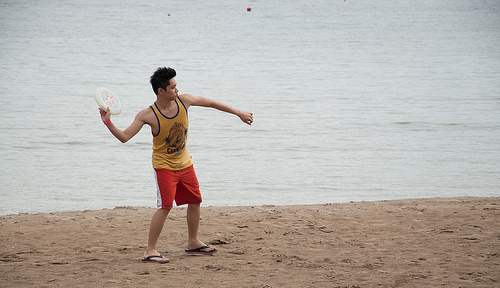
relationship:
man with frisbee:
[93, 66, 253, 263] [73, 57, 139, 134]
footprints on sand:
[0, 193, 494, 285] [359, 204, 480, 278]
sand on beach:
[0, 193, 495, 284] [1, 1, 498, 286]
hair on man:
[149, 65, 176, 97] [93, 66, 253, 263]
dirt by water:
[0, 194, 498, 286] [1, 0, 498, 216]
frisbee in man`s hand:
[94, 85, 122, 117] [96, 106, 113, 125]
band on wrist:
[102, 120, 111, 127] [98, 116, 116, 131]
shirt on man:
[144, 97, 198, 171] [93, 66, 253, 263]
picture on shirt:
[163, 116, 188, 155] [138, 95, 195, 173]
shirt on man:
[138, 95, 195, 173] [93, 66, 253, 263]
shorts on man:
[154, 165, 202, 210] [104, 45, 224, 252]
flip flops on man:
[141, 243, 217, 264] [101, 44, 223, 281]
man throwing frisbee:
[93, 66, 253, 263] [96, 86, 122, 115]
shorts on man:
[155, 165, 202, 203] [93, 66, 253, 263]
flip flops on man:
[141, 241, 216, 266] [93, 66, 253, 263]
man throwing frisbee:
[93, 66, 253, 263] [90, 84, 127, 117]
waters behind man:
[254, 6, 496, 173] [105, 46, 289, 258]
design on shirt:
[158, 120, 193, 159] [141, 99, 199, 174]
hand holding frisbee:
[100, 112, 110, 122] [89, 82, 123, 113]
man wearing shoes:
[93, 66, 253, 263] [138, 238, 218, 264]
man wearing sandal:
[93, 66, 253, 263] [132, 250, 172, 267]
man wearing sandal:
[93, 66, 253, 263] [180, 240, 220, 260]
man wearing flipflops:
[81, 50, 262, 272] [121, 241, 229, 267]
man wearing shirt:
[93, 66, 253, 263] [129, 87, 230, 173]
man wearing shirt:
[93, 66, 253, 263] [144, 95, 191, 172]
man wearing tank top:
[93, 66, 253, 263] [148, 97, 193, 170]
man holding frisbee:
[93, 66, 253, 263] [93, 85, 123, 115]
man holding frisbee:
[93, 66, 253, 263] [88, 80, 133, 117]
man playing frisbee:
[93, 66, 253, 263] [93, 85, 125, 117]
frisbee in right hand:
[94, 85, 122, 117] [96, 106, 113, 123]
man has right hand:
[93, 66, 253, 263] [96, 106, 113, 123]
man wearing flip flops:
[93, 66, 253, 263] [132, 241, 220, 267]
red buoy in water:
[239, 4, 256, 18] [5, 5, 496, 187]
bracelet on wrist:
[101, 115, 113, 128] [95, 114, 110, 122]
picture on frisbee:
[101, 94, 118, 109] [90, 80, 123, 119]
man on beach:
[93, 66, 253, 263] [6, 192, 468, 282]